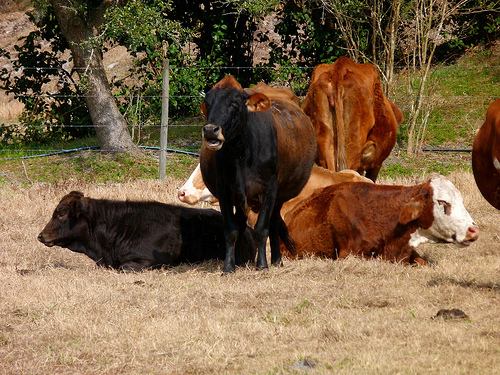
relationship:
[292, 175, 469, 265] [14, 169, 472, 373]
cow sitting in field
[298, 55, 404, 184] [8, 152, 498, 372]
cow standing in field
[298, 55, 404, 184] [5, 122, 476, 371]
cow sitting in field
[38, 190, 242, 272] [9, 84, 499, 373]
cow sitting in field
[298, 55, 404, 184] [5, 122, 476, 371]
cow standing in field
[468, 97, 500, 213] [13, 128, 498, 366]
cow standing in field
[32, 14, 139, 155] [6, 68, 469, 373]
tree growing in field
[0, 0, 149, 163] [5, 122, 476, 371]
tree growing in field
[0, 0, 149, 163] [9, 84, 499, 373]
tree growing in field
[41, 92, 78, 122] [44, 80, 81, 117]
leaf growing on stem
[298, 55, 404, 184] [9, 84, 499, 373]
cow in field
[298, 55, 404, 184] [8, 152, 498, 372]
cow in field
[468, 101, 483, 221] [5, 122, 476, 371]
cow in field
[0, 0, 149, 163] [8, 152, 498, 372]
tree in field